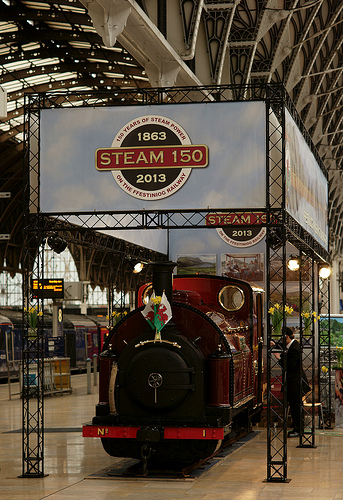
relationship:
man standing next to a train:
[270, 326, 311, 439] [74, 257, 313, 475]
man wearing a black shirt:
[270, 326, 311, 439] [269, 352, 300, 423]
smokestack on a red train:
[87, 271, 195, 453] [127, 251, 287, 293]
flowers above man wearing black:
[107, 309, 194, 455] [73, 366, 230, 492]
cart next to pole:
[35, 357, 70, 395] [84, 357, 91, 395]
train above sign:
[80, 268, 260, 498] [31, 275, 66, 302]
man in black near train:
[268, 326, 310, 436] [84, 256, 264, 466]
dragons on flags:
[143, 299, 171, 324] [137, 287, 180, 345]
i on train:
[201, 427, 205, 438] [80, 268, 260, 498]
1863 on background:
[134, 127, 167, 145] [118, 124, 179, 186]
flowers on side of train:
[264, 298, 328, 340] [73, 245, 285, 498]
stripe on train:
[79, 421, 226, 444] [72, 250, 280, 479]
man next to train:
[270, 326, 311, 439] [84, 256, 264, 466]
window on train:
[218, 285, 248, 309] [89, 251, 275, 379]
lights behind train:
[285, 250, 332, 279] [80, 255, 283, 470]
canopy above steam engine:
[19, 71, 336, 266] [86, 243, 291, 467]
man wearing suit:
[270, 326, 311, 439] [281, 343, 311, 428]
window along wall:
[1, 238, 161, 310] [8, 228, 339, 319]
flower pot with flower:
[269, 336, 280, 347] [285, 305, 297, 314]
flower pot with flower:
[269, 336, 280, 347] [283, 305, 289, 314]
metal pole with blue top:
[92, 353, 98, 384] [90, 352, 96, 357]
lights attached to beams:
[287, 258, 330, 278] [269, 210, 330, 267]